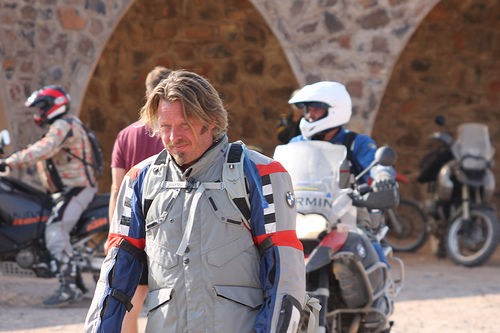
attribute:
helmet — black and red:
[13, 85, 77, 137]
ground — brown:
[0, 230, 499, 331]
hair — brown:
[143, 67, 230, 142]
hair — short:
[165, 79, 220, 129]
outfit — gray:
[318, 132, 380, 174]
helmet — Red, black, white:
[22, 82, 87, 130]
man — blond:
[86, 62, 316, 329]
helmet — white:
[289, 86, 346, 116]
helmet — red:
[25, 88, 65, 115]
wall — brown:
[248, 106, 308, 183]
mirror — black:
[373, 144, 398, 165]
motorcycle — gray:
[412, 158, 497, 260]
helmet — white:
[285, 79, 351, 139]